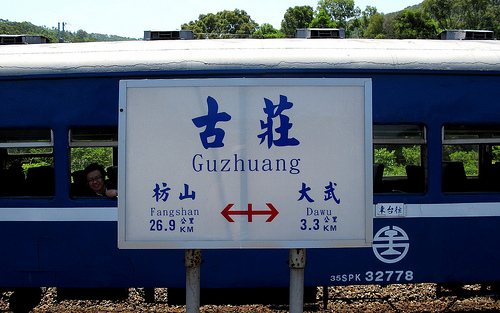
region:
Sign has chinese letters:
[108, 71, 380, 259]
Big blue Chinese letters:
[174, 87, 313, 157]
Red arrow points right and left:
[215, 192, 285, 229]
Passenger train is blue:
[8, 20, 497, 295]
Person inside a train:
[78, 161, 113, 209]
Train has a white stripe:
[0, 191, 499, 228]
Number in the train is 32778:
[360, 266, 422, 289]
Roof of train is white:
[1, 22, 498, 77]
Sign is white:
[108, 71, 383, 256]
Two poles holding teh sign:
[181, 247, 309, 311]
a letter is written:
[188, 149, 206, 175]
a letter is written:
[204, 155, 219, 173]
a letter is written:
[219, 154, 234, 176]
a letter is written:
[229, 152, 244, 174]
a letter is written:
[247, 156, 257, 172]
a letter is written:
[262, 153, 272, 173]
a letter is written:
[273, 152, 288, 179]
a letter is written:
[288, 149, 299, 181]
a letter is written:
[191, 91, 236, 156]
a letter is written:
[254, 86, 304, 157]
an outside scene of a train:
[0, 0, 498, 310]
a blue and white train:
[0, 37, 496, 307]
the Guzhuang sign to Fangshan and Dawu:
[119, 78, 373, 248]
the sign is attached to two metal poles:
[287, 246, 307, 312]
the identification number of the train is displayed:
[328, 268, 414, 282]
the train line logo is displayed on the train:
[373, 225, 410, 265]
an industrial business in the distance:
[48, 19, 69, 32]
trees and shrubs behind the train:
[178, 0, 499, 36]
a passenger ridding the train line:
[69, 144, 117, 206]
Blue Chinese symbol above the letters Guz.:
[193, 92, 230, 149]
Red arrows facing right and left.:
[218, 201, 278, 225]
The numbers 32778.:
[363, 270, 413, 282]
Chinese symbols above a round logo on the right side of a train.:
[376, 203, 406, 218]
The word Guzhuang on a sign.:
[193, 153, 301, 175]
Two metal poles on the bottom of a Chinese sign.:
[183, 248, 308, 312]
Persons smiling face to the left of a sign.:
[81, 162, 110, 192]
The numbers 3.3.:
[298, 216, 320, 233]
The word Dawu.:
[304, 207, 332, 216]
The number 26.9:
[148, 218, 177, 230]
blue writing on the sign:
[185, 151, 305, 181]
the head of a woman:
[77, 153, 107, 200]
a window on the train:
[66, 119, 122, 207]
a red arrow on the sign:
[217, 199, 284, 233]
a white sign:
[113, 74, 380, 256]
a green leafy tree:
[174, 7, 262, 38]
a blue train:
[1, 36, 496, 296]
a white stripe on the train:
[0, 204, 499, 225]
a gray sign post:
[284, 246, 310, 311]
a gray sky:
[0, 1, 426, 39]